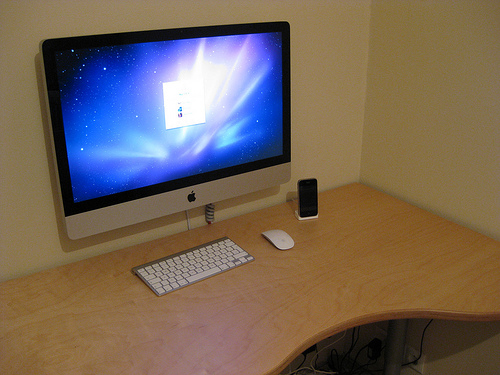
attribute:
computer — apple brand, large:
[37, 21, 291, 241]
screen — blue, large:
[53, 30, 283, 204]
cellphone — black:
[297, 177, 317, 217]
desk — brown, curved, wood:
[0, 179, 499, 375]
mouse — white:
[259, 229, 294, 251]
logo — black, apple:
[186, 190, 197, 203]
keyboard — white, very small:
[131, 235, 255, 297]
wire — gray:
[184, 210, 191, 233]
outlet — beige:
[403, 347, 427, 373]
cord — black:
[402, 316, 434, 367]